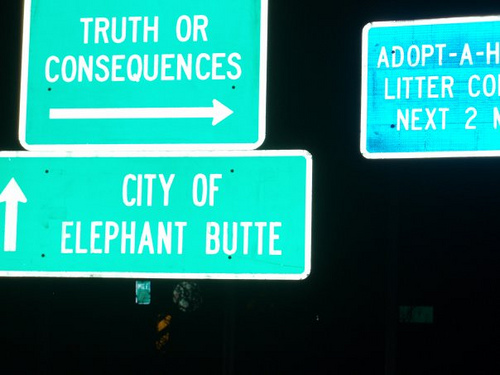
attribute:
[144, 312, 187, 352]
pole — yellow, black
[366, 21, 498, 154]
sign — adopt-a-highway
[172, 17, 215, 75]
window — small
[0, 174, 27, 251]
arrow — white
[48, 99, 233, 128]
arrow — long, white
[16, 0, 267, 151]
sign — advising, pointing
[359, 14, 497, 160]
sign — advising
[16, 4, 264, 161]
board — green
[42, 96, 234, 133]
arrow — white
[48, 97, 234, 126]
arrow — pointing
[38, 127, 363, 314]
board — rectangle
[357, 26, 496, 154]
sign — advising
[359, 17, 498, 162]
street sign — green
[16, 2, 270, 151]
street sign — green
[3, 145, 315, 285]
street sign — green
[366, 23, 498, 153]
board color — green, blue, white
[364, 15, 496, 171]
sign — green, posted